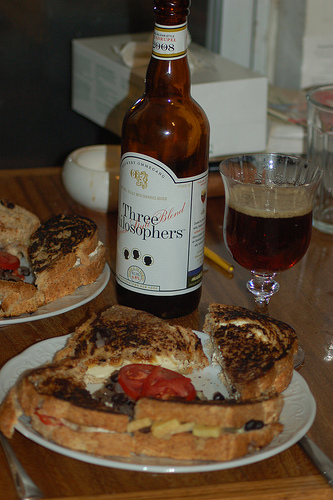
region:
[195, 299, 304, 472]
toasted bread on plate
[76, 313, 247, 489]
toasted bread on plate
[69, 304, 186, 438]
toasted bread on plate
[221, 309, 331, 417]
toasted bread on plate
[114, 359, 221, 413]
A slice of red tomatoe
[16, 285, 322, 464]
A sandwich sliced into four pieces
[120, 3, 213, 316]
A brown bottle of beer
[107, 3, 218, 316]
A brown bottle with white label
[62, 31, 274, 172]
A white box of kleenex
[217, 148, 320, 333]
A Glass filled with beer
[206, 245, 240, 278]
A yellow pencil on the table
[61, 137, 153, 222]
A little round white dish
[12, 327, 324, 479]
A round white plate with sandwich on it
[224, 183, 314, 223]
Foam on top of liquid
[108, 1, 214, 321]
a tall beverage bottle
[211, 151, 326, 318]
a glass full of a beverage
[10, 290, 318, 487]
a delicious looking sandwich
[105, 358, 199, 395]
a red tomato slice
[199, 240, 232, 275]
a yellow colored pencil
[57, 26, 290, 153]
a box of tissues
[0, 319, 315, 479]
a white plate full of food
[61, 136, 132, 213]
a small white bowl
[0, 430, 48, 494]
a piece of silverware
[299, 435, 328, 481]
a piece of silverware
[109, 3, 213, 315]
a large bottle of wine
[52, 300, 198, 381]
a browned sandwich slice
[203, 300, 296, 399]
a browned sandwich slice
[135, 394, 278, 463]
a browned sandwich slice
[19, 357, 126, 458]
a browned sandwich slice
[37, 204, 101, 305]
a browned sandwich slice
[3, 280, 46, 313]
a browned sandwich slice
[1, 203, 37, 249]
a browned sandwich slice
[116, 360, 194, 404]
a slice of red tomato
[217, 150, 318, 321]
a fluted glass of wine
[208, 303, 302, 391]
grilled half of sandwich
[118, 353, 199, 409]
slice of tomato on plate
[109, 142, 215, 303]
white label on bottle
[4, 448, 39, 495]
handle of utensil on table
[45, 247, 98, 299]
crust of brown bread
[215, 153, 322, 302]
ale in glass with stem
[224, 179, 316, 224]
head on ale surface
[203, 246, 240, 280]
yellow pencil on table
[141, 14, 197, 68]
label on neck of bottle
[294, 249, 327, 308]
refelction on wood table